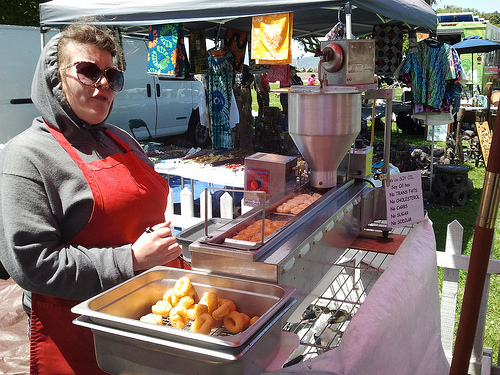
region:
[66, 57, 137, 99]
The woman is wearing sunglasses.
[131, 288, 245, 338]
Onion rings in the pan.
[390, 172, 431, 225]
Sign on the rack.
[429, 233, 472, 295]
The fence is white.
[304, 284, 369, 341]
The rack is wired.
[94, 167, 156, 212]
The apron is red.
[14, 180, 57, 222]
The sweater is grey.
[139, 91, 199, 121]
The van is white.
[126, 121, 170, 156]
Chair against the van.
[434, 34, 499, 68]
The umbrella is blue.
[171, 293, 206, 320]
doughnuts in the pan.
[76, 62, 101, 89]
sunglasses on woman's face.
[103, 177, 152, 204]
red apron on woman.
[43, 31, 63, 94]
hood over woman's ears.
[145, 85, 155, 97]
door handle on van.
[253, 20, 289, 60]
yellow handkerchief hanging from tent.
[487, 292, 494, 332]
grass on the ground.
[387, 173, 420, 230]
sign with writing on it.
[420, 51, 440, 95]
shirt with colorful design.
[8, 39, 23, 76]
side of white van.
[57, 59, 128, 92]
the woman's sunglasses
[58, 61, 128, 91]
the sunglasses on the woman's face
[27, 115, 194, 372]
the red apron on the woman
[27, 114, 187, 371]
the woman's red apron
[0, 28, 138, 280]
the gray hoodie on the woman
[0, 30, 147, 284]
the woman's gray hoodie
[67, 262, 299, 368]
the gray trays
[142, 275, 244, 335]
the food in the gray trays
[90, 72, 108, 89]
the nose on the woman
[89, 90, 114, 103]
the mouth on the woman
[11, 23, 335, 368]
Flea market food stand.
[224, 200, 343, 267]
Doughnuts deep frying oil.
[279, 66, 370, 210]
Dough funneled overhead oil.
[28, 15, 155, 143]
Woman dark hair sunglasses.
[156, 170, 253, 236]
White picket fence separaters.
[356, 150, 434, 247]
Food prices clearly shown.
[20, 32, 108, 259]
Gray hoodie keeps warm.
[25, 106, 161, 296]
Red apron protects splashes.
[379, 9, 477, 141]
Hawaiian print shirts hang.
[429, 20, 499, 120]
Blue umbrella upper right.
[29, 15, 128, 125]
the head of a woman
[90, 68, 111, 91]
the nose of a woman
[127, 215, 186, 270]
the hand of a woman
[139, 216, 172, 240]
the thumb of a woman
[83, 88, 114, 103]
the mouth of a woman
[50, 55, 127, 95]
a pair of sunglasses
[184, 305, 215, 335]
a round yellow donut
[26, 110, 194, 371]
a red apron on the woman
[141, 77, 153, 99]
a black van door handle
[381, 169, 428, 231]
a white paper